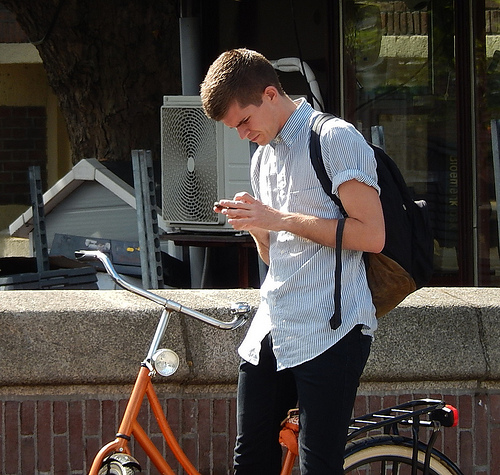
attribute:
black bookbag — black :
[319, 125, 449, 330]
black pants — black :
[224, 294, 389, 473]